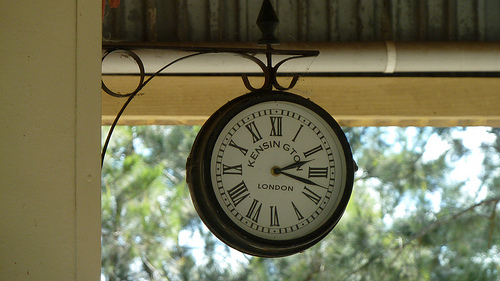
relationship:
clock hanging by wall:
[183, 90, 362, 260] [3, 1, 106, 279]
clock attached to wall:
[183, 90, 362, 260] [3, 1, 106, 279]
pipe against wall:
[91, 41, 499, 76] [3, 1, 106, 279]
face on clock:
[211, 102, 345, 242] [203, 122, 352, 207]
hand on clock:
[269, 151, 314, 176] [172, 92, 350, 257]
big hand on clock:
[165, 106, 390, 241] [183, 90, 362, 260]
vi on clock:
[266, 202, 286, 234] [212, 97, 343, 244]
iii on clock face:
[302, 162, 331, 183] [205, 99, 347, 241]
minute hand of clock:
[273, 170, 316, 186] [152, 81, 410, 265]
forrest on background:
[99, 115, 495, 262] [107, 121, 498, 225]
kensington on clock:
[245, 142, 305, 169] [183, 90, 362, 260]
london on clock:
[256, 179, 291, 192] [183, 90, 362, 260]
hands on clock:
[272, 155, 327, 190] [183, 90, 362, 260]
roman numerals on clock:
[223, 115, 330, 226] [183, 90, 362, 260]